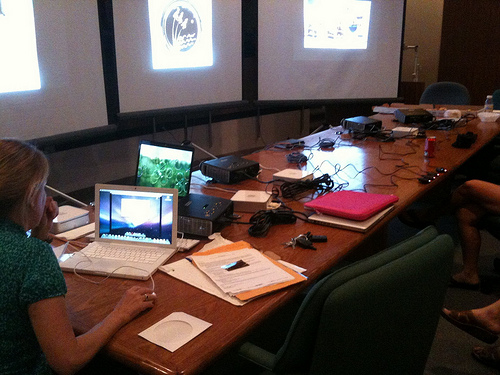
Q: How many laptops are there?
A: 3.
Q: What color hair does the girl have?
A: Blonde.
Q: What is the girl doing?
A: Using the laptop.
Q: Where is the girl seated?
A: At a large conference table.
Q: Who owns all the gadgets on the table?
A: The company.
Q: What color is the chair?
A: The chair is green.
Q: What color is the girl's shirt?
A: Green.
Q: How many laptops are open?
A: 2.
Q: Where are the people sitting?
A: Table.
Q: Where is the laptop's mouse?
A: Girl's hand.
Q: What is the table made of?
A: Wood.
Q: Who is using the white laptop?
A: Girl.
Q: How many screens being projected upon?
A: 3.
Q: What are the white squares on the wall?
A: Projection screens.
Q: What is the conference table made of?
A: Wood.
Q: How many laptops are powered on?
A: Two.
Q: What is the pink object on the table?
A: Laptop.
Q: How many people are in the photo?
A: Three.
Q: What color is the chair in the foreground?
A: Dark green.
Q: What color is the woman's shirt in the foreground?
A: Green.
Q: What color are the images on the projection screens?
A: Black and white.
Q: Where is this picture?
A: In an office.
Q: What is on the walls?
A: Projection screens.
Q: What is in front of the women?
A: A laptop.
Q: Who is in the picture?
A: A woman.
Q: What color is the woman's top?
A: Blue.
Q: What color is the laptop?
A: White.